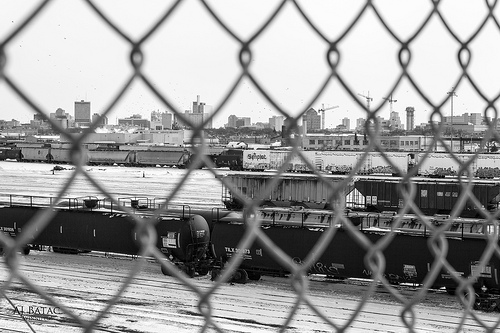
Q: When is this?
A: Daytime.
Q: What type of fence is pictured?
A: Chain link fence.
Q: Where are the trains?
A: On the tracks.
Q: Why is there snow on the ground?
A: It is winter.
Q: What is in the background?
A: A city.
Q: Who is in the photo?
A: No one is in the photo.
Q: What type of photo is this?
A: Black and white.